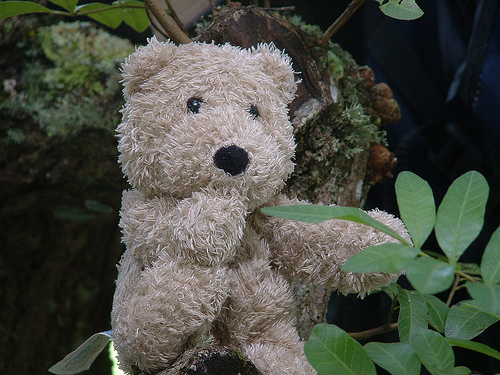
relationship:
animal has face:
[109, 32, 409, 375] [116, 43, 296, 202]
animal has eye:
[109, 32, 409, 375] [179, 79, 205, 117]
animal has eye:
[109, 32, 409, 375] [241, 95, 267, 116]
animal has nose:
[109, 32, 409, 375] [217, 144, 263, 168]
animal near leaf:
[109, 32, 409, 375] [400, 166, 431, 245]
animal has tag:
[109, 32, 409, 375] [47, 327, 144, 374]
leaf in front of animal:
[400, 166, 431, 245] [109, 32, 409, 375]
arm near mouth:
[143, 195, 251, 264] [209, 167, 264, 213]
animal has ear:
[109, 32, 409, 375] [127, 39, 170, 75]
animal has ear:
[109, 32, 409, 375] [252, 39, 294, 94]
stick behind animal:
[315, 0, 381, 41] [109, 32, 409, 375]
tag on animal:
[47, 327, 144, 374] [112, 30, 394, 374]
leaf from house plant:
[400, 166, 431, 245] [347, 202, 497, 374]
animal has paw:
[109, 32, 409, 375] [184, 193, 267, 264]